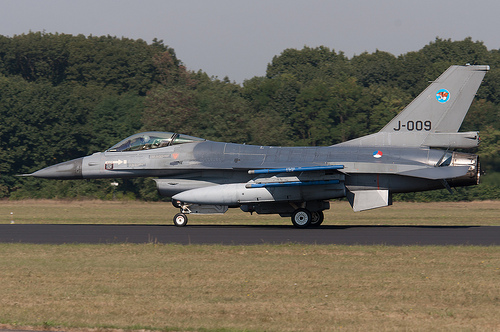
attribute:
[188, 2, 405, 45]
sky — clear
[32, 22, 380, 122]
trees — green, in distance, leafy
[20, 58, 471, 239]
jet — grey, military, fighter, gray, taking off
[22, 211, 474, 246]
runway — clear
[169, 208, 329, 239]
wheels — down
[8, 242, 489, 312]
grass — brown, dying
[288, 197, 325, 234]
wheels — rear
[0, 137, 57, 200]
nose — pointed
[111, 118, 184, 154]
cockpit — clear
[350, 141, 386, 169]
brand — red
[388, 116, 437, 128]
number — black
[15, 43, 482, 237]
plane — grey